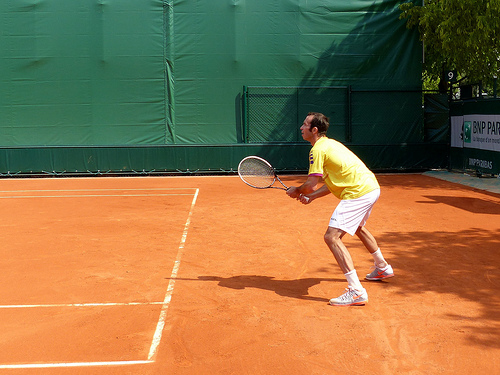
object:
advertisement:
[449, 114, 500, 150]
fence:
[237, 84, 500, 145]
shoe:
[327, 285, 370, 308]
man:
[281, 110, 398, 308]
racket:
[236, 155, 311, 201]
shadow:
[164, 273, 373, 305]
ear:
[311, 127, 318, 135]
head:
[298, 111, 332, 142]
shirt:
[307, 136, 382, 201]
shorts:
[326, 187, 383, 237]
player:
[282, 106, 396, 306]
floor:
[3, 171, 498, 374]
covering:
[1, 1, 425, 176]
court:
[0, 174, 499, 375]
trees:
[480, 0, 500, 96]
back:
[339, 129, 387, 307]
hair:
[304, 110, 333, 135]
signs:
[449, 111, 500, 178]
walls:
[446, 110, 500, 176]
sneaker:
[365, 264, 397, 282]